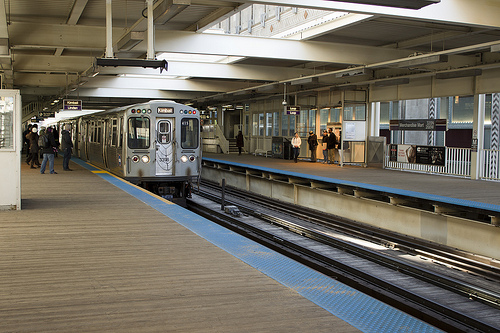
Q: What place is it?
A: It is a station.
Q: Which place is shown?
A: It is a station.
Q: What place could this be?
A: It is a station.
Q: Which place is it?
A: It is a station.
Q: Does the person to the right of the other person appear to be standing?
A: Yes, the person is standing.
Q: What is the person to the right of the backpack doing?
A: The person is standing.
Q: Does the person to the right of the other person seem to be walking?
A: No, the person is standing.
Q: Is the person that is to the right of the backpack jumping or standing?
A: The person is standing.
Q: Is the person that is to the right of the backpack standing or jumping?
A: The person is standing.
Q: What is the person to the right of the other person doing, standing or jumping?
A: The person is standing.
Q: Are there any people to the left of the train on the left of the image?
A: Yes, there is a person to the left of the train.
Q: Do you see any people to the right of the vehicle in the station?
A: No, the person is to the left of the train.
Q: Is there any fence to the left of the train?
A: No, there is a person to the left of the train.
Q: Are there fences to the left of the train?
A: No, there is a person to the left of the train.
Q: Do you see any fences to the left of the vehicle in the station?
A: No, there is a person to the left of the train.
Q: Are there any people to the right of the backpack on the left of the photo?
A: Yes, there is a person to the right of the backpack.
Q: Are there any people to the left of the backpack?
A: No, the person is to the right of the backpack.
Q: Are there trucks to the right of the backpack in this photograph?
A: No, there is a person to the right of the backpack.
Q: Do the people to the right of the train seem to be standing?
A: Yes, the people are standing.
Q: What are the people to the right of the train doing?
A: The people are standing.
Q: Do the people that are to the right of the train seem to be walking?
A: No, the people are standing.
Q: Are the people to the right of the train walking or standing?
A: The people are standing.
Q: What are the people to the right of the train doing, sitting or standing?
A: The people are standing.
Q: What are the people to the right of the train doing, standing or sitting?
A: The people are standing.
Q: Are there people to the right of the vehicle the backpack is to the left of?
A: Yes, there are people to the right of the train.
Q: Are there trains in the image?
A: Yes, there is a train.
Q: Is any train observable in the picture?
A: Yes, there is a train.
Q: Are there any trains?
A: Yes, there is a train.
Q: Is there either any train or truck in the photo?
A: Yes, there is a train.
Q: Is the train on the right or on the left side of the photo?
A: The train is on the left of the image.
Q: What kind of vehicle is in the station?
A: The vehicle is a train.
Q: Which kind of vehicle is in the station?
A: The vehicle is a train.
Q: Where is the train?
A: The train is in the station.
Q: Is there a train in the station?
A: Yes, there is a train in the station.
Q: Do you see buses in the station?
A: No, there is a train in the station.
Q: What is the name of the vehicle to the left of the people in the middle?
A: The vehicle is a train.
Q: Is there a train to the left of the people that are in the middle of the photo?
A: Yes, there is a train to the left of the people.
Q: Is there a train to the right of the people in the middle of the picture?
A: No, the train is to the left of the people.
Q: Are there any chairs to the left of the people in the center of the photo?
A: No, there is a train to the left of the people.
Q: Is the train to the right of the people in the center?
A: No, the train is to the left of the people.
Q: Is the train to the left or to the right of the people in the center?
A: The train is to the left of the people.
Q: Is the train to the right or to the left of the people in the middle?
A: The train is to the left of the people.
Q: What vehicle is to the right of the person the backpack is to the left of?
A: The vehicle is a train.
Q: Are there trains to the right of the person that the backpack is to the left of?
A: Yes, there is a train to the right of the person.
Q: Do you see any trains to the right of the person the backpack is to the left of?
A: Yes, there is a train to the right of the person.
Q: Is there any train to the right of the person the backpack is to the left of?
A: Yes, there is a train to the right of the person.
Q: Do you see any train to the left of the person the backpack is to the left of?
A: No, the train is to the right of the person.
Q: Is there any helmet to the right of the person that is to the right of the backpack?
A: No, there is a train to the right of the person.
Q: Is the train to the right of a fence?
A: No, the train is to the right of the person.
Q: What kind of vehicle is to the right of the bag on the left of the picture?
A: The vehicle is a train.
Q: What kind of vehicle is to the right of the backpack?
A: The vehicle is a train.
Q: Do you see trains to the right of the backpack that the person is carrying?
A: Yes, there is a train to the right of the backpack.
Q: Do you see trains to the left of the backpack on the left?
A: No, the train is to the right of the backpack.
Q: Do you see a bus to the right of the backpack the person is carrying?
A: No, there is a train to the right of the backpack.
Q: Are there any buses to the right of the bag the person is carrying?
A: No, there is a train to the right of the backpack.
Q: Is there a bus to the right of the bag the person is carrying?
A: No, there is a train to the right of the backpack.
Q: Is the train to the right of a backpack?
A: Yes, the train is to the right of a backpack.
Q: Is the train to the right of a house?
A: No, the train is to the right of a backpack.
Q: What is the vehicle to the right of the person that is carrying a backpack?
A: The vehicle is a train.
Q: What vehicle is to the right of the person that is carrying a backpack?
A: The vehicle is a train.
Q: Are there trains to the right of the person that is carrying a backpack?
A: Yes, there is a train to the right of the person.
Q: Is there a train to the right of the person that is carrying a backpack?
A: Yes, there is a train to the right of the person.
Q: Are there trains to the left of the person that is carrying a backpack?
A: No, the train is to the right of the person.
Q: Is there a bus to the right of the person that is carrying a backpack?
A: No, there is a train to the right of the person.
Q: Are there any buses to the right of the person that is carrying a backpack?
A: No, there is a train to the right of the person.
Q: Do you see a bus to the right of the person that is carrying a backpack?
A: No, there is a train to the right of the person.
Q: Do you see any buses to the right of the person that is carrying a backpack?
A: No, there is a train to the right of the person.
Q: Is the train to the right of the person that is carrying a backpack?
A: Yes, the train is to the right of the person.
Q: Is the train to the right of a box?
A: No, the train is to the right of the person.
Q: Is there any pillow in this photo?
A: No, there are no pillows.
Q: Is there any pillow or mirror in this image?
A: No, there are no pillows or mirrors.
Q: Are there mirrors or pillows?
A: No, there are no pillows or mirrors.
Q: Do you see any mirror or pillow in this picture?
A: No, there are no pillows or mirrors.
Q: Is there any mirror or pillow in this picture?
A: No, there are no pillows or mirrors.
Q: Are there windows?
A: Yes, there are windows.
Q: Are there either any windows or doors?
A: Yes, there are windows.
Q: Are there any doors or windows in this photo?
A: Yes, there are windows.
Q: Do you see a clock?
A: No, there are no clocks.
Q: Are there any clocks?
A: No, there are no clocks.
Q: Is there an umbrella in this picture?
A: No, there are no umbrellas.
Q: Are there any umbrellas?
A: No, there are no umbrellas.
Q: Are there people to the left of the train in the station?
A: Yes, there are people to the left of the train.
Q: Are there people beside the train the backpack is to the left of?
A: Yes, there are people beside the train.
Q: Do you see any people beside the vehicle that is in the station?
A: Yes, there are people beside the train.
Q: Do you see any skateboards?
A: No, there are no skateboards.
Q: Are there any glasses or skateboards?
A: No, there are no skateboards or glasses.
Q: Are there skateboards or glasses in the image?
A: No, there are no skateboards or glasses.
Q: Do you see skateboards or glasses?
A: No, there are no skateboards or glasses.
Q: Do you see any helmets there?
A: No, there are no helmets.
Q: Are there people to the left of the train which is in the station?
A: Yes, there is a person to the left of the train.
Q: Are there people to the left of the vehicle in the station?
A: Yes, there is a person to the left of the train.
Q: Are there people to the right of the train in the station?
A: No, the person is to the left of the train.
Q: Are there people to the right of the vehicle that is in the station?
A: No, the person is to the left of the train.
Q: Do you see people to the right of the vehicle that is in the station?
A: No, the person is to the left of the train.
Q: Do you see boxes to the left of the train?
A: No, there is a person to the left of the train.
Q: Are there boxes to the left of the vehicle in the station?
A: No, there is a person to the left of the train.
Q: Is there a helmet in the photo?
A: No, there are no helmets.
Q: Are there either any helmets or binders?
A: No, there are no helmets or binders.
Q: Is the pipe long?
A: Yes, the pipe is long.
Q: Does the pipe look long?
A: Yes, the pipe is long.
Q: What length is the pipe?
A: The pipe is long.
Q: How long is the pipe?
A: The pipe is long.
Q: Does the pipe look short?
A: No, the pipe is long.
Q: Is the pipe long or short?
A: The pipe is long.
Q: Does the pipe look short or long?
A: The pipe is long.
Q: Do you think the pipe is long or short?
A: The pipe is long.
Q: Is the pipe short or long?
A: The pipe is long.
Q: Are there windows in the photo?
A: Yes, there are windows.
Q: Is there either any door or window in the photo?
A: Yes, there are windows.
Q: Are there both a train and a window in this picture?
A: Yes, there are both a window and a train.